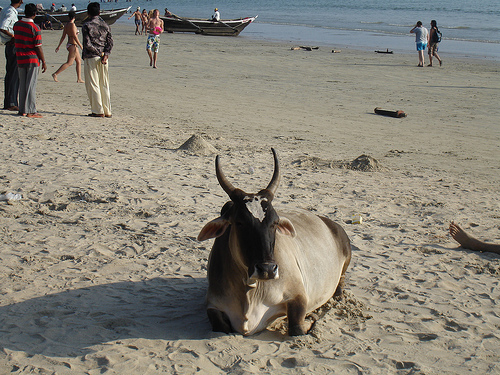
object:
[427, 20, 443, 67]
person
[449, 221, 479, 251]
foot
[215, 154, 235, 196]
horns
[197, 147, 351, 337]
bull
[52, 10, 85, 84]
person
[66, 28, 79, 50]
bikini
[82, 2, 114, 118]
man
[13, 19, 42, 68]
shirt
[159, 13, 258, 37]
boat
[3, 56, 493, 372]
sand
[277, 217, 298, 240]
ear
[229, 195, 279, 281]
cow face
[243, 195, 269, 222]
marking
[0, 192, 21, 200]
white lid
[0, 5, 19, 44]
white shirt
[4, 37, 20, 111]
dark pants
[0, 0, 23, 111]
man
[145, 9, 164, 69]
man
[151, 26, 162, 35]
frisbee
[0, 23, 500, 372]
beach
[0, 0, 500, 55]
water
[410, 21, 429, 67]
people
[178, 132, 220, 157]
shape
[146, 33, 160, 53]
trunks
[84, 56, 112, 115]
pants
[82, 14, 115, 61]
shirt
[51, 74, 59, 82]
foot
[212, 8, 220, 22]
people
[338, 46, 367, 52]
edge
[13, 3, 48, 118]
man